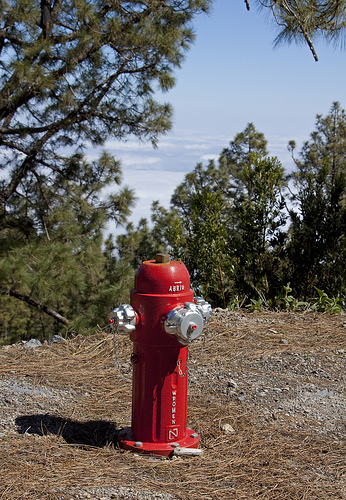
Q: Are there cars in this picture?
A: No, there are no cars.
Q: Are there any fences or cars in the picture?
A: No, there are no cars or fences.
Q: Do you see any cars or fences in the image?
A: No, there are no cars or fences.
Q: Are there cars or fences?
A: No, there are no cars or fences.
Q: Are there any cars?
A: No, there are no cars.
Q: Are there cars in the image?
A: No, there are no cars.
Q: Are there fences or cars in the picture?
A: No, there are no cars or fences.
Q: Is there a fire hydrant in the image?
A: Yes, there is a fire hydrant.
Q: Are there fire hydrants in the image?
A: Yes, there is a fire hydrant.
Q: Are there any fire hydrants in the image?
A: Yes, there is a fire hydrant.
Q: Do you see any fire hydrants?
A: Yes, there is a fire hydrant.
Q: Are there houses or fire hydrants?
A: Yes, there is a fire hydrant.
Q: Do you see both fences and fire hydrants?
A: No, there is a fire hydrant but no fences.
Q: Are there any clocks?
A: No, there are no clocks.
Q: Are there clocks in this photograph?
A: No, there are no clocks.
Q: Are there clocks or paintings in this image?
A: No, there are no clocks or paintings.